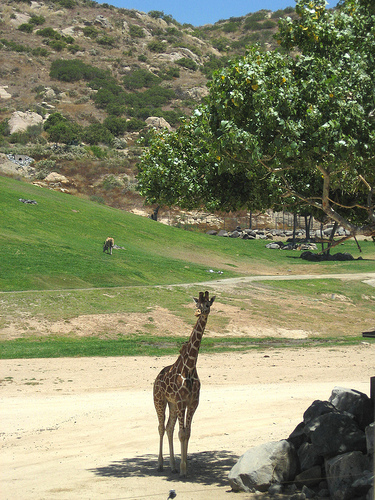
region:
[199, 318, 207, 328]
brown spot on giraffe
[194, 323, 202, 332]
brown spot on giraffe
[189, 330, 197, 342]
brown spot on giraffe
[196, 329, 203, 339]
brown spot on giraffe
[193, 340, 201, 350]
brown spot on giraffe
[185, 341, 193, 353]
brown spot on giraffe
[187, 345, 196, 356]
brown spot on giraffe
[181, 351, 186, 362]
brown spot on giraffe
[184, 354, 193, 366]
brown spot on giraffe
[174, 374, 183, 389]
brown spot on giraffe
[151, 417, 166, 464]
leg of a giraffe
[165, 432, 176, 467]
leg of a giraffe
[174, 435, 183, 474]
leg of a giraffe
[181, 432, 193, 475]
leg of a giraffe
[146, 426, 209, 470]
legs of a giraffe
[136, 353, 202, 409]
body of a giraffe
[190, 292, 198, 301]
ear of a giraffe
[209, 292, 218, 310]
ear of a giraffe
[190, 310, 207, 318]
mouth of a giraffe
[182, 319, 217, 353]
a neck of a giraffe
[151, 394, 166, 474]
the long brown and white leg of the giraffe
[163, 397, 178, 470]
the long brown and white leg of the giraffe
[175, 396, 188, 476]
the long brown and white leg of the giraffe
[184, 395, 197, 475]
the long brown and white leg of the giraffe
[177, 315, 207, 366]
the long neck of the giraffe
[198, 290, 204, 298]
the horn of the giraffe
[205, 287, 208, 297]
the horn of the giraffe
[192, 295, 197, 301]
the ear of the giraffe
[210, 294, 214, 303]
the horn of the giraffe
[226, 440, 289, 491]
the large grey stone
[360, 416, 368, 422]
part of a rock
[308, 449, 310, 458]
edge of a rock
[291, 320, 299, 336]
part of a grass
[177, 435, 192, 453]
edge of a leg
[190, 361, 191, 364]
part of a neck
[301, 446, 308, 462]
part of a stone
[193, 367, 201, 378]
part of a neck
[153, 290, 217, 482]
Giraffe facing the camera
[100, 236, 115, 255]
Animal in the background eating grass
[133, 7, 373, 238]
Large tree to the right of the giraffe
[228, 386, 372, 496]
Rocks to the right of the giraffe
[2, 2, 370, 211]
Hills behind giraffe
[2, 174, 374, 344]
Green grass on hill behind giraffe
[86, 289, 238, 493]
Giraffe standing in the shade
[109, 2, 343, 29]
Blue sky behind hills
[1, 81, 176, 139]
Rocks in the hills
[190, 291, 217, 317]
Head of giraffe